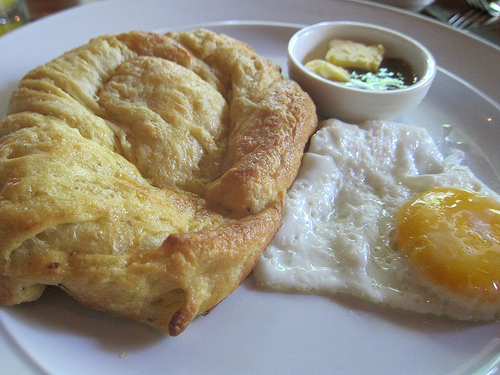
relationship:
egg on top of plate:
[252, 116, 496, 324] [5, 6, 496, 370]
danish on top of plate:
[5, 29, 319, 336] [5, 6, 496, 370]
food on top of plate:
[7, 20, 496, 335] [5, 6, 496, 370]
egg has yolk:
[252, 116, 496, 324] [389, 188, 495, 302]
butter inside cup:
[328, 35, 385, 73] [288, 21, 436, 124]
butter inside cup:
[301, 58, 354, 85] [288, 21, 436, 124]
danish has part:
[5, 29, 319, 336] [168, 296, 199, 337]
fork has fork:
[446, 2, 496, 34] [446, 2, 496, 34]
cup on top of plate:
[288, 21, 436, 124] [5, 6, 496, 370]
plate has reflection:
[5, 6, 496, 370] [487, 114, 491, 125]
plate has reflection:
[5, 6, 496, 370] [464, 342, 496, 369]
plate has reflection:
[5, 6, 496, 370] [222, 20, 250, 30]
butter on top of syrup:
[328, 35, 385, 73] [342, 54, 418, 92]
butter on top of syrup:
[301, 58, 354, 85] [342, 54, 418, 92]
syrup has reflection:
[342, 54, 418, 92] [347, 66, 417, 90]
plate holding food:
[5, 6, 496, 370] [7, 20, 496, 335]